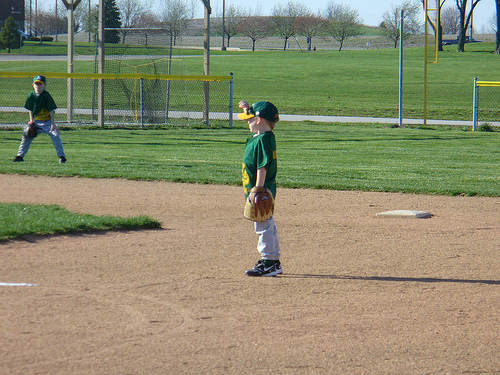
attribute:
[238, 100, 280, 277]
child — playing, here, young, shielding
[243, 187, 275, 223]
glove — brown, here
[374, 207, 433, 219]
base — here, white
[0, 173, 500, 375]
dirt — brown, here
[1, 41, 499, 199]
grass — short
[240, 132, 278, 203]
jersey — green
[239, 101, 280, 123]
cap — green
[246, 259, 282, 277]
cleats — black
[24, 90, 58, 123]
jersey — green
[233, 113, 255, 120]
bill — yellow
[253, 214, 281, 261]
pants — white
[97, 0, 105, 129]
pole — gray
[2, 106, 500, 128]
sidewalk — here